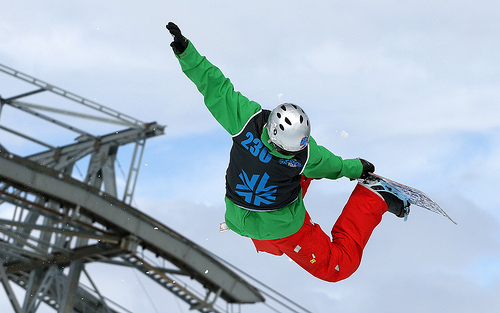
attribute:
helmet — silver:
[262, 100, 311, 152]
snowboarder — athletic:
[157, 22, 437, 282]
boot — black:
[356, 170, 413, 222]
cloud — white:
[330, 12, 452, 128]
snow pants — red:
[250, 176, 390, 283]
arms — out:
[149, 20, 384, 188]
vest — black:
[218, 132, 325, 217]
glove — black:
[148, 16, 185, 61]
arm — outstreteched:
[113, 42, 244, 130]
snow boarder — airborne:
[137, 10, 475, 289]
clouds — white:
[339, 65, 424, 130]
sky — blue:
[330, 17, 453, 122]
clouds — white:
[1, 2, 498, 132]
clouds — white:
[330, 0, 499, 181]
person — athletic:
[163, 18, 412, 285]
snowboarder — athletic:
[166, 28, 419, 279]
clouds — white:
[320, 32, 490, 142]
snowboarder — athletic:
[103, 29, 485, 281]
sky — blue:
[81, 7, 491, 310]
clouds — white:
[391, 92, 498, 139]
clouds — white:
[414, 249, 499, 299]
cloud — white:
[2, 1, 497, 171]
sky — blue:
[0, 1, 498, 311]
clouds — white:
[0, 0, 499, 311]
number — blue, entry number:
[239, 128, 270, 165]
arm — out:
[147, 12, 269, 135]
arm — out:
[305, 132, 374, 195]